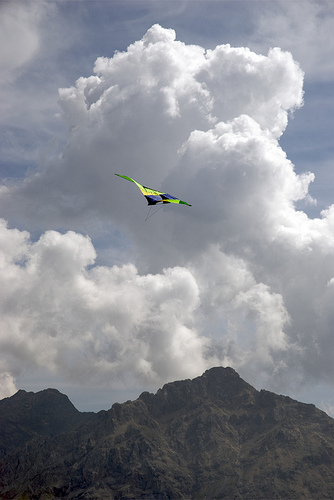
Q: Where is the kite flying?
A: By the mountain.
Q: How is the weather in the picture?
A: Cloudy.